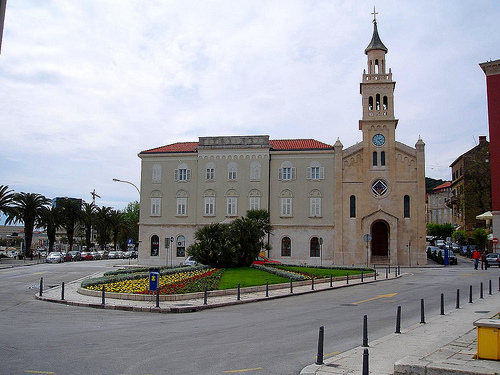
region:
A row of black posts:
[300, 280, 490, 372]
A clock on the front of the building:
[333, 19, 433, 263]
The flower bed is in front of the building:
[80, 251, 360, 301]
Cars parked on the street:
[40, 232, 128, 269]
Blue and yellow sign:
[141, 259, 163, 299]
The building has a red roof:
[140, 134, 340, 256]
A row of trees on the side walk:
[10, 187, 134, 260]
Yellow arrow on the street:
[347, 284, 395, 315]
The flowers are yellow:
[79, 260, 219, 294]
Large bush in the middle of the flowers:
[181, 207, 277, 280]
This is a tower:
[357, 3, 408, 178]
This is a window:
[151, 159, 166, 188]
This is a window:
[146, 189, 169, 221]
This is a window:
[149, 230, 161, 257]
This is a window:
[170, 229, 189, 261]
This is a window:
[174, 189, 193, 223]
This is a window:
[173, 161, 190, 186]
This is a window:
[199, 157, 218, 186]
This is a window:
[199, 190, 219, 216]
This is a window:
[224, 159, 238, 186]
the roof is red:
[173, 128, 304, 168]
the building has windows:
[151, 162, 422, 262]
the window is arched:
[286, 228, 335, 256]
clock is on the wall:
[356, 129, 396, 171]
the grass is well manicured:
[215, 257, 277, 295]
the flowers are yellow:
[114, 265, 179, 286]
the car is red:
[253, 248, 283, 275]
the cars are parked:
[432, 233, 455, 275]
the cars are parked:
[51, 245, 133, 267]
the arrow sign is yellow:
[338, 283, 404, 325]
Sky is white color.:
[41, 37, 203, 112]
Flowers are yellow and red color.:
[103, 263, 235, 307]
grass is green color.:
[213, 250, 265, 290]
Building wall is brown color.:
[144, 160, 426, 260]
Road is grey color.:
[46, 330, 156, 372]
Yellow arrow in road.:
[348, 275, 419, 323]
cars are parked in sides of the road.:
[413, 222, 496, 284]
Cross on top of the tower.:
[350, 3, 432, 118]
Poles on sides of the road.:
[304, 301, 499, 355]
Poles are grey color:
[316, 298, 460, 365]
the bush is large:
[176, 219, 270, 276]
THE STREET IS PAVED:
[3, 234, 498, 374]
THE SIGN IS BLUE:
[138, 263, 169, 300]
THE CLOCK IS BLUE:
[364, 133, 390, 153]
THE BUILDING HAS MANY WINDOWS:
[140, 144, 417, 256]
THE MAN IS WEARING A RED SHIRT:
[470, 250, 482, 272]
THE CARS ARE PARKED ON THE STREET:
[43, 245, 140, 265]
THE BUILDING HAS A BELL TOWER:
[352, 25, 406, 179]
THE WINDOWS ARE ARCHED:
[346, 188, 412, 227]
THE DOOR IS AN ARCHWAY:
[363, 207, 398, 274]